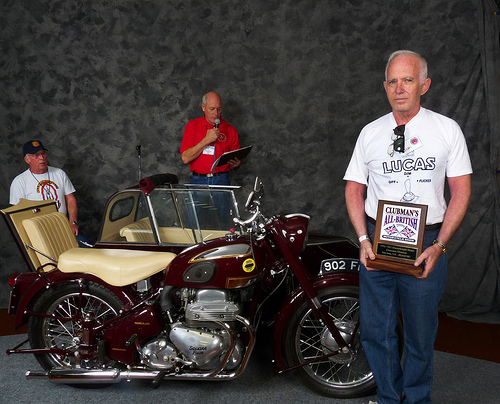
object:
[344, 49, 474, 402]
man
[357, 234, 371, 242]
watch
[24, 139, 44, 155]
cap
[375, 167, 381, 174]
ground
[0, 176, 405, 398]
motorcycle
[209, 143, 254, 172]
clipboard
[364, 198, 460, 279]
metal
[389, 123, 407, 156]
glasses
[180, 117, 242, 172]
shirt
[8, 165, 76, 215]
shirt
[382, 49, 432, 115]
head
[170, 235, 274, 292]
tank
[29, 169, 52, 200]
necklace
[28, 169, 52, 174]
neck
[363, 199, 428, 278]
board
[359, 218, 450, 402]
jeans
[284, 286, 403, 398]
front wheel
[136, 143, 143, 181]
microphone stand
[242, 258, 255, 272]
sticker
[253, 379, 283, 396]
floor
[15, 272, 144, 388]
wheel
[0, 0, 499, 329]
cloth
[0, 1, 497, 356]
wall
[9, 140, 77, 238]
man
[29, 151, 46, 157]
eyeglasses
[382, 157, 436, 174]
letters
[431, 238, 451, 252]
watch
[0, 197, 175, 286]
seat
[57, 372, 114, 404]
floor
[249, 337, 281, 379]
shade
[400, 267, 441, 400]
leg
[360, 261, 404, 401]
leg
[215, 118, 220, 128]
microphone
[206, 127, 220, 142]
hand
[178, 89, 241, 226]
man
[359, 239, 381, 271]
hands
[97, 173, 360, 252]
side car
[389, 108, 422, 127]
collar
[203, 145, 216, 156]
tag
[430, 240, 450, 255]
wrist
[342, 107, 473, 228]
shirt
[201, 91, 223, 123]
head